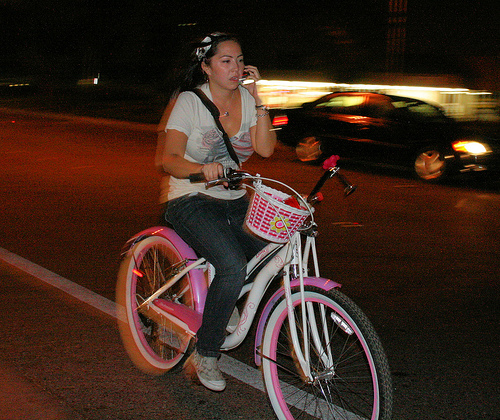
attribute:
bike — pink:
[113, 155, 395, 419]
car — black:
[268, 90, 497, 185]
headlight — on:
[451, 140, 493, 157]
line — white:
[0, 238, 395, 419]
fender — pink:
[255, 275, 342, 370]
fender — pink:
[122, 225, 218, 313]